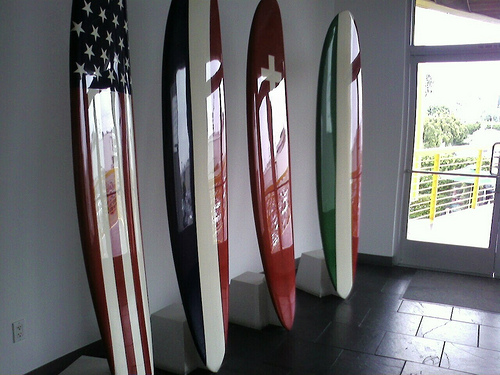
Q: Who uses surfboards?
A: Surfers.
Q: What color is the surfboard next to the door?
A: Green, white, and red.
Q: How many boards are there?
A: Four.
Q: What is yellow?
A: Railing.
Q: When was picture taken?
A: Daytime.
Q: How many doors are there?
A: One.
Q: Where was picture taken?
A: Along the surfboard wall.